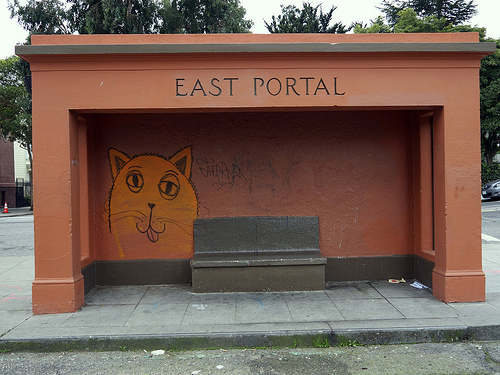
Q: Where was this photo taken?
A: East Portal.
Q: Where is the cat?
A: Behind and to the left of the bench.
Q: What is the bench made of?
A: Cement.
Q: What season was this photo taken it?
A: Summer.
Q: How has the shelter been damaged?
A: With graffiti.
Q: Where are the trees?
A: Behind the shelter.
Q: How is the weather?
A: Overcast.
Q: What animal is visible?
A: Cat.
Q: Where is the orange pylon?
A: Behind the shelter and to the left.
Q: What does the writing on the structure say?
A: East Portal.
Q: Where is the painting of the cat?
A: On the structure.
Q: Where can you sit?
A: On the bench.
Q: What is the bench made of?
A: Concrete?.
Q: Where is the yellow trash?
A: On the right.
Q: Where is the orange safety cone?
A: In the back on the left.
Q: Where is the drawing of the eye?
A: On the cat.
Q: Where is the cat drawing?
A: In the waiting shed.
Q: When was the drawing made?
A: Last week.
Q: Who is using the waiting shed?
A: No one.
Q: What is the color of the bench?
A: Gray.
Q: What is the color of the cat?
A: Orange.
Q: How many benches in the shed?
A: One.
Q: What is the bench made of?
A: Cement.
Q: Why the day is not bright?
A: It's gloomy.